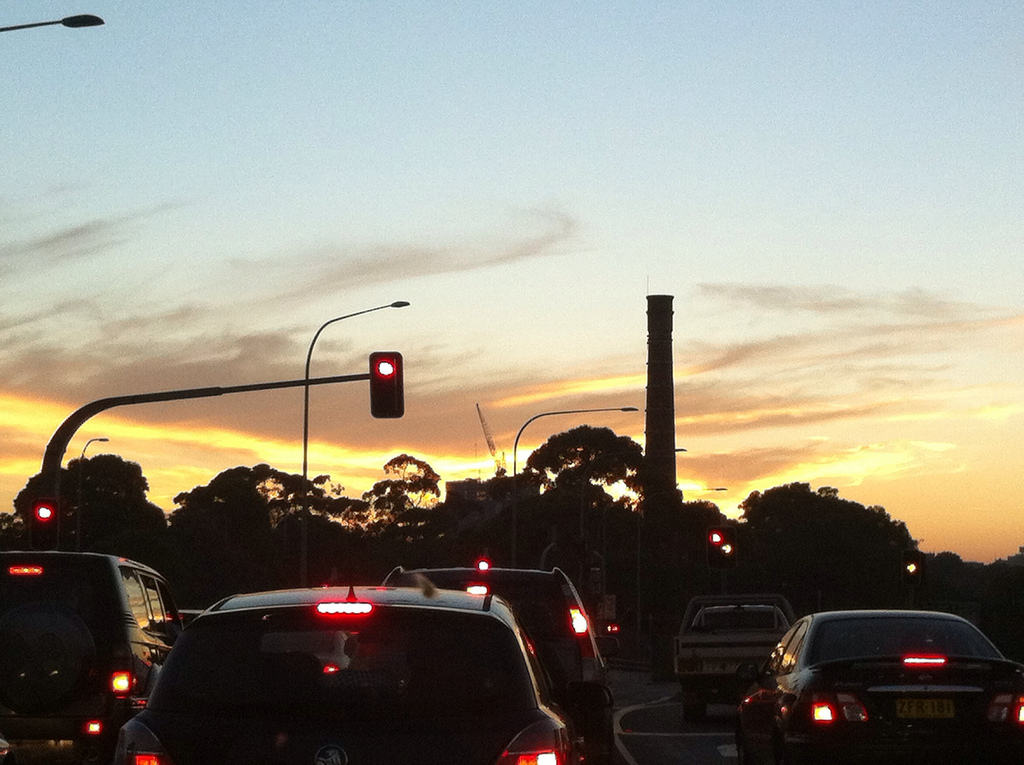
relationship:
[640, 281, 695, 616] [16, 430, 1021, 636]
tower behind trees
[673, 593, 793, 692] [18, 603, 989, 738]
truck on road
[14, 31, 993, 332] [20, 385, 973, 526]
sky fading to yellow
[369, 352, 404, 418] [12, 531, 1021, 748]
light above road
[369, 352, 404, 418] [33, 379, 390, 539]
light attached to pole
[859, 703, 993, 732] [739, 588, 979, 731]
plate on car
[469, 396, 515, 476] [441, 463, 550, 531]
crane on top of building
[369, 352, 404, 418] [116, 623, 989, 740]
light overhanging road